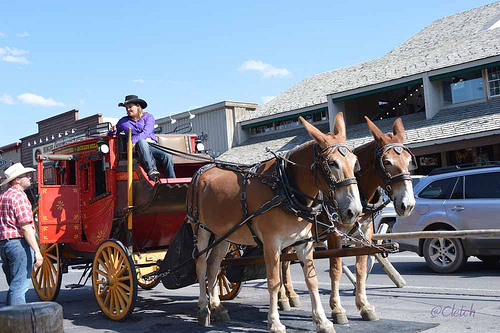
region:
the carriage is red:
[89, 213, 106, 226]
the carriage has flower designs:
[54, 198, 66, 212]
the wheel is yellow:
[98, 256, 125, 288]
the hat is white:
[11, 165, 26, 175]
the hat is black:
[127, 93, 136, 103]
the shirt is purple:
[133, 121, 148, 131]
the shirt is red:
[7, 200, 22, 216]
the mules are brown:
[222, 178, 242, 198]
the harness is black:
[268, 165, 304, 204]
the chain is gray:
[338, 226, 365, 249]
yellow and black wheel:
[86, 238, 138, 320]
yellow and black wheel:
[31, 241, 68, 301]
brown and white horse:
[176, 108, 359, 331]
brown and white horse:
[324, 100, 424, 320]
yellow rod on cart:
[117, 117, 144, 239]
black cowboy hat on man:
[109, 86, 149, 108]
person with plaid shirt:
[0, 157, 40, 307]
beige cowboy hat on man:
[1, 155, 38, 190]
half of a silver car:
[388, 165, 496, 264]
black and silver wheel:
[424, 228, 456, 267]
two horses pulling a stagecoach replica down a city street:
[26, 58, 456, 325]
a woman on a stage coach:
[97, 92, 180, 184]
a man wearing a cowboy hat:
[0, 162, 46, 299]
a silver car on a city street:
[396, 170, 496, 267]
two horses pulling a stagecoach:
[59, 108, 428, 326]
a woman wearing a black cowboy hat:
[111, 89, 158, 126]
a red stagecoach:
[33, 136, 195, 327]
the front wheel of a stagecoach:
[84, 237, 139, 321]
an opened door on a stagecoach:
[30, 145, 92, 261]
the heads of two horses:
[294, 105, 427, 235]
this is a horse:
[185, 116, 365, 331]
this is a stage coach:
[30, 107, 205, 268]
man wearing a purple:
[119, 110, 162, 139]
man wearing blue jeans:
[128, 136, 171, 171]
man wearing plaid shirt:
[3, 184, 52, 248]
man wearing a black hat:
[114, 88, 146, 108]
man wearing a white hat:
[0, 165, 32, 182]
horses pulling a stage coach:
[30, 93, 420, 316]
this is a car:
[372, 112, 494, 284]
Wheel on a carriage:
[92, 238, 136, 319]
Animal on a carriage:
[182, 112, 334, 332]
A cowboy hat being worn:
[0, 161, 40, 186]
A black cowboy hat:
[117, 95, 147, 109]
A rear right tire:
[422, 225, 460, 272]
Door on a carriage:
[37, 153, 83, 243]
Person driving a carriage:
[109, 94, 174, 176]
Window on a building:
[441, 71, 488, 106]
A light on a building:
[185, 108, 195, 120]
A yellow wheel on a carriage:
[91, 237, 138, 319]